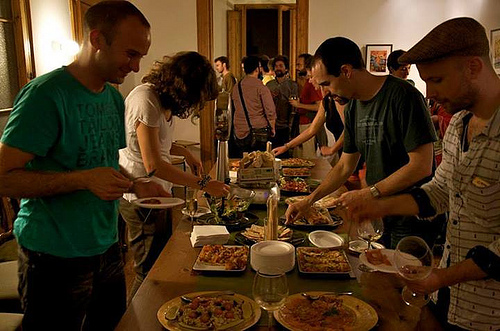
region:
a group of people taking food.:
[11, 0, 492, 322]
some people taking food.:
[37, 8, 477, 303]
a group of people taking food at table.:
[27, 13, 482, 301]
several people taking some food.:
[42, 10, 482, 298]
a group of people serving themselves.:
[20, 9, 487, 301]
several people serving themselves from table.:
[12, 8, 486, 300]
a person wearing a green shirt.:
[2, 11, 160, 256]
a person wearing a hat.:
[377, 8, 498, 202]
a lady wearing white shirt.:
[128, 42, 211, 184]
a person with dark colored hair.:
[297, 26, 373, 116]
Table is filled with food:
[123, 155, 435, 328]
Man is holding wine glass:
[356, 30, 499, 330]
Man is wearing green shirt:
[0, 0, 185, 327]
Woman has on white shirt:
[118, 48, 231, 300]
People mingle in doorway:
[196, 2, 310, 157]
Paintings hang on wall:
[310, 1, 499, 95]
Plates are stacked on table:
[243, 236, 300, 279]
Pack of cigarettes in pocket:
[468, 173, 499, 228]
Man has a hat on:
[396, 16, 497, 159]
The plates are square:
[191, 234, 358, 286]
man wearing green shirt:
[0, 4, 161, 329]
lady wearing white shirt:
[108, 27, 236, 282]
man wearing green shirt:
[302, 37, 458, 259]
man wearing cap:
[389, 12, 499, 329]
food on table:
[157, 104, 428, 329]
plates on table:
[247, 227, 302, 298]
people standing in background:
[218, 41, 335, 183]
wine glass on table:
[255, 254, 305, 329]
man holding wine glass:
[386, 212, 498, 320]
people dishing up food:
[5, 7, 498, 316]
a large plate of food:
[156, 285, 269, 328]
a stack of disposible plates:
[244, 238, 300, 275]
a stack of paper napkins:
[189, 218, 232, 248]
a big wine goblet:
[388, 234, 458, 316]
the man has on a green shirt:
[2, 55, 157, 265]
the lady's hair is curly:
[147, 40, 220, 155]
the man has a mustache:
[305, 37, 371, 114]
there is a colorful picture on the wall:
[357, 32, 411, 83]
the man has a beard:
[271, 50, 296, 95]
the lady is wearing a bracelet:
[178, 169, 233, 206]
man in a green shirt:
[0, 25, 161, 272]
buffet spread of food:
[151, 133, 396, 325]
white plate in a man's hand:
[134, 168, 184, 217]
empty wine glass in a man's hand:
[382, 222, 445, 312]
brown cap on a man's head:
[394, 3, 495, 113]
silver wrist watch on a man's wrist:
[364, 183, 385, 199]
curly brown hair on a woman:
[137, 42, 228, 138]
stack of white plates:
[247, 232, 298, 281]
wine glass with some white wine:
[249, 257, 289, 329]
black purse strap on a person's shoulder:
[233, 70, 273, 152]